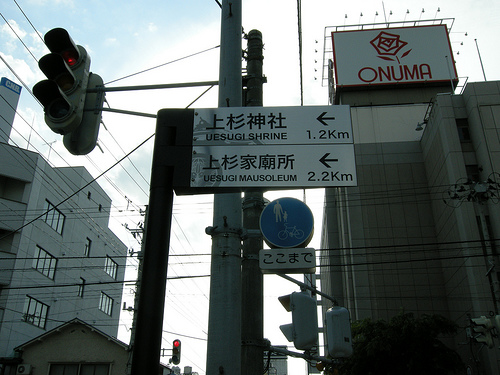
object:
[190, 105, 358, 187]
sign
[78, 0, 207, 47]
sky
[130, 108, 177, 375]
pole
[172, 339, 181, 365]
light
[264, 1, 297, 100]
clouds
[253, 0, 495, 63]
sky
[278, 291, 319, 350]
sign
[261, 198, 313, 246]
sign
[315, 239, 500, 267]
wires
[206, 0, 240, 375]
pole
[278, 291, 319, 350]
traffic light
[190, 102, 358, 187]
street sign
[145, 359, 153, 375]
ground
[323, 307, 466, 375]
tree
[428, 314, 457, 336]
leaves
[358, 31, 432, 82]
sign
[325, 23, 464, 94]
onuma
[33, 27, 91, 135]
stop light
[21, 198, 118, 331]
windows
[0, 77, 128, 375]
building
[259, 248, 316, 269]
sign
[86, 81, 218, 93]
pole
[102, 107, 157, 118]
pole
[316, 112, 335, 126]
arrows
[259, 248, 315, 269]
rectangle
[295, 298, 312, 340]
side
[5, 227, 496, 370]
street